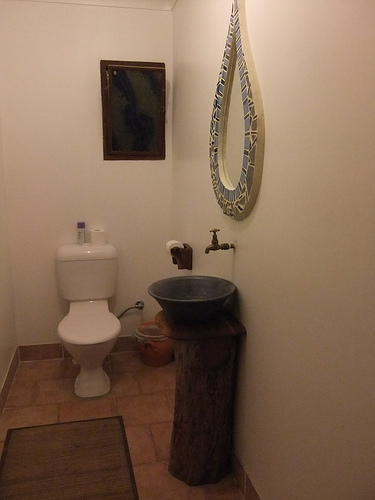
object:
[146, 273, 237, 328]
sink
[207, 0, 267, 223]
mirror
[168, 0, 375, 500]
wall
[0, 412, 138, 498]
rug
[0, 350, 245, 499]
floor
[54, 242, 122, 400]
toilet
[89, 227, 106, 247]
tissue